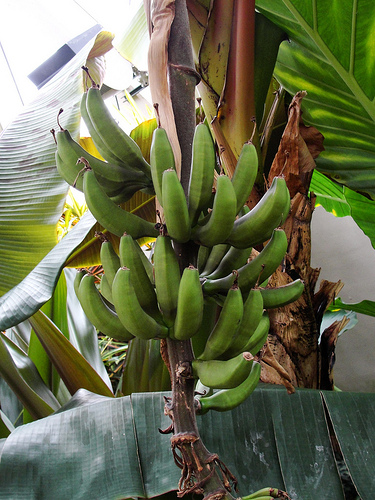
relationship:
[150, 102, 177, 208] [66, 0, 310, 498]
banana growing tree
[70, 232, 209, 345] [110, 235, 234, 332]
bananas curving upwards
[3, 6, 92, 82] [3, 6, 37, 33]
sun shining sky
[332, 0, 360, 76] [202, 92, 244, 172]
vein growing spine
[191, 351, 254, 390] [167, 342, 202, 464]
banana attached stem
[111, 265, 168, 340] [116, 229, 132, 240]
banana has nub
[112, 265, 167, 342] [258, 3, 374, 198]
banana grows on plant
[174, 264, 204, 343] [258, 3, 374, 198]
banana grows on plant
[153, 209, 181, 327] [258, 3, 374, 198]
banana grows on plant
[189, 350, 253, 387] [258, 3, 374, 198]
banana grows on plant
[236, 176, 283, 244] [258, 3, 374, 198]
banana grows on plant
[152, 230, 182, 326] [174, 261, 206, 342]
banana next to banana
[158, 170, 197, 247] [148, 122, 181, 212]
banana under banana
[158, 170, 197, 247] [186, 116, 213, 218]
banana under banana